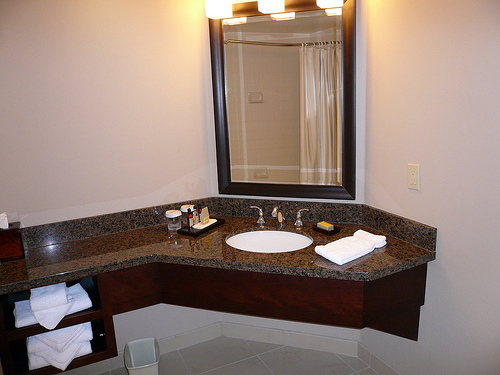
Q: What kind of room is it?
A: It is a bathroom.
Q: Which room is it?
A: It is a bathroom.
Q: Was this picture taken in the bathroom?
A: Yes, it was taken in the bathroom.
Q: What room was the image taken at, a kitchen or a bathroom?
A: It was taken at a bathroom.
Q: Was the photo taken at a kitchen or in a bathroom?
A: It was taken at a bathroom.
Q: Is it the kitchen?
A: No, it is the bathroom.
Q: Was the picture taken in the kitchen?
A: No, the picture was taken in the bathroom.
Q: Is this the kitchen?
A: No, it is the bathroom.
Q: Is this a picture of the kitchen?
A: No, the picture is showing the bathroom.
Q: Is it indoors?
A: Yes, it is indoors.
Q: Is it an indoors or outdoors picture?
A: It is indoors.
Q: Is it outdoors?
A: No, it is indoors.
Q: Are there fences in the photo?
A: No, there are no fences.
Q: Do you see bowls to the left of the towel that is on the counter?
A: Yes, there is a bowl to the left of the towel.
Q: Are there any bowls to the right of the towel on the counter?
A: No, the bowl is to the left of the towel.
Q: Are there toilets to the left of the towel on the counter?
A: No, there is a bowl to the left of the towel.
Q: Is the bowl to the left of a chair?
A: No, the bowl is to the left of a towel.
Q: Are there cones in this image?
A: No, there are no cones.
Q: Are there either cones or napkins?
A: No, there are no cones or napkins.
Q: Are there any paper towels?
A: No, there are no paper towels.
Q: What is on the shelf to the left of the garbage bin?
A: The towels are on the shelf.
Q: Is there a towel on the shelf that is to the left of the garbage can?
A: Yes, there are towels on the shelf.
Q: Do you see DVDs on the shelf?
A: No, there are towels on the shelf.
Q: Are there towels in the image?
A: Yes, there is a towel.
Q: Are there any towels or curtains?
A: Yes, there is a towel.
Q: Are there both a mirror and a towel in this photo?
A: Yes, there are both a towel and a mirror.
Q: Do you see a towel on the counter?
A: Yes, there is a towel on the counter.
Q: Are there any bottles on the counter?
A: No, there is a towel on the counter.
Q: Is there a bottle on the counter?
A: No, there is a towel on the counter.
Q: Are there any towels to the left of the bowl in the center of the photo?
A: No, the towel is to the right of the bowl.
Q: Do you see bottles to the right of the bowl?
A: No, there is a towel to the right of the bowl.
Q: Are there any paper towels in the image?
A: No, there are no paper towels.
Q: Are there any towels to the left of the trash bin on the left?
A: Yes, there are towels to the left of the trash bin.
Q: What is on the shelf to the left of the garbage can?
A: The towels are on the shelf.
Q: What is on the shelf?
A: The towels are on the shelf.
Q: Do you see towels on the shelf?
A: Yes, there are towels on the shelf.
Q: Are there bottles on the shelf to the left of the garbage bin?
A: No, there are towels on the shelf.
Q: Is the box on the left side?
A: Yes, the box is on the left of the image.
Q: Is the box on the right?
A: No, the box is on the left of the image.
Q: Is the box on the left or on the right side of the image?
A: The box is on the left of the image.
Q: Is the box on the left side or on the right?
A: The box is on the left of the image.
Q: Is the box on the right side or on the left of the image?
A: The box is on the left of the image.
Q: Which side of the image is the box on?
A: The box is on the left of the image.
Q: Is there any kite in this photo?
A: No, there are no kites.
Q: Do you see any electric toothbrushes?
A: No, there are no electric toothbrushes.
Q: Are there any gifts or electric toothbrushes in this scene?
A: No, there are no electric toothbrushes or gifts.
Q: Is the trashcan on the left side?
A: Yes, the trashcan is on the left of the image.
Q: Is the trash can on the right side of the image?
A: No, the trash can is on the left of the image.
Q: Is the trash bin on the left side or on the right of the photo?
A: The trash bin is on the left of the image.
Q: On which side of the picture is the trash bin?
A: The trash bin is on the left of the image.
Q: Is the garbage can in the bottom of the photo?
A: Yes, the garbage can is in the bottom of the image.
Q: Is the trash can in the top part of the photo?
A: No, the trash can is in the bottom of the image.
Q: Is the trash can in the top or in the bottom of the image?
A: The trash can is in the bottom of the image.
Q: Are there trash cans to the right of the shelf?
A: Yes, there is a trash can to the right of the shelf.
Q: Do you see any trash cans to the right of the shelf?
A: Yes, there is a trash can to the right of the shelf.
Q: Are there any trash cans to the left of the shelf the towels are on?
A: No, the trash can is to the right of the shelf.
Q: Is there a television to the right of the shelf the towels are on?
A: No, there is a trash can to the right of the shelf.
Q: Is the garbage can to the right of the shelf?
A: Yes, the garbage can is to the right of the shelf.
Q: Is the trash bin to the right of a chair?
A: No, the trash bin is to the right of the shelf.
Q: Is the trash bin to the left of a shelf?
A: No, the trash bin is to the right of a shelf.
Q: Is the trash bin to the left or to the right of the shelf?
A: The trash bin is to the right of the shelf.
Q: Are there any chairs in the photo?
A: No, there are no chairs.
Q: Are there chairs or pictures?
A: No, there are no chairs or pictures.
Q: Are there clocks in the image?
A: No, there are no clocks.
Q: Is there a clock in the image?
A: No, there are no clocks.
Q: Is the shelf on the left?
A: Yes, the shelf is on the left of the image.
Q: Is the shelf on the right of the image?
A: No, the shelf is on the left of the image.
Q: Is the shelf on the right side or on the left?
A: The shelf is on the left of the image.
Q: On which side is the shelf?
A: The shelf is on the left of the image.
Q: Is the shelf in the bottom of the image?
A: Yes, the shelf is in the bottom of the image.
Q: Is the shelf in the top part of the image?
A: No, the shelf is in the bottom of the image.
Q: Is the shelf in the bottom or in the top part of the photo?
A: The shelf is in the bottom of the image.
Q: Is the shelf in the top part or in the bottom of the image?
A: The shelf is in the bottom of the image.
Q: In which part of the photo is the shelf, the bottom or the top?
A: The shelf is in the bottom of the image.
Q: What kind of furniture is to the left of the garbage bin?
A: The piece of furniture is a shelf.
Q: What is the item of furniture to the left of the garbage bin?
A: The piece of furniture is a shelf.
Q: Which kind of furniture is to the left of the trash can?
A: The piece of furniture is a shelf.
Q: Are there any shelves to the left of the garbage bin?
A: Yes, there is a shelf to the left of the garbage bin.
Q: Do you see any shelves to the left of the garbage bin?
A: Yes, there is a shelf to the left of the garbage bin.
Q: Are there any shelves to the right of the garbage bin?
A: No, the shelf is to the left of the garbage bin.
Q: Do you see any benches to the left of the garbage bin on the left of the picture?
A: No, there is a shelf to the left of the trashcan.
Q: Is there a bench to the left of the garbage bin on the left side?
A: No, there is a shelf to the left of the trashcan.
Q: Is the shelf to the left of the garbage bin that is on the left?
A: Yes, the shelf is to the left of the garbage can.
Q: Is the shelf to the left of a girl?
A: No, the shelf is to the left of the garbage can.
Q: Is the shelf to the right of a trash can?
A: No, the shelf is to the left of a trash can.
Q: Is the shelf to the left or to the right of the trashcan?
A: The shelf is to the left of the trashcan.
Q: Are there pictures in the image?
A: No, there are no pictures.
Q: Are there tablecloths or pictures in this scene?
A: No, there are no pictures or tablecloths.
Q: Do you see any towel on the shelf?
A: Yes, there are towels on the shelf.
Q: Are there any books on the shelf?
A: No, there are towels on the shelf.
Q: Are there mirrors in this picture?
A: Yes, there is a mirror.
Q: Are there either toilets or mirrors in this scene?
A: Yes, there is a mirror.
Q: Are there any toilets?
A: No, there are no toilets.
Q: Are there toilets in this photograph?
A: No, there are no toilets.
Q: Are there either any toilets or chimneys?
A: No, there are no toilets or chimneys.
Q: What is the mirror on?
A: The mirror is on the wall.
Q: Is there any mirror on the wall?
A: Yes, there is a mirror on the wall.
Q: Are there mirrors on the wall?
A: Yes, there is a mirror on the wall.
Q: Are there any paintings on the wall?
A: No, there is a mirror on the wall.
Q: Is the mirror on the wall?
A: Yes, the mirror is on the wall.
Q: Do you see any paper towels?
A: No, there are no paper towels.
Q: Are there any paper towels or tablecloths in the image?
A: No, there are no paper towels or tablecloths.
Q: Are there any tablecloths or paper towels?
A: No, there are no paper towels or tablecloths.